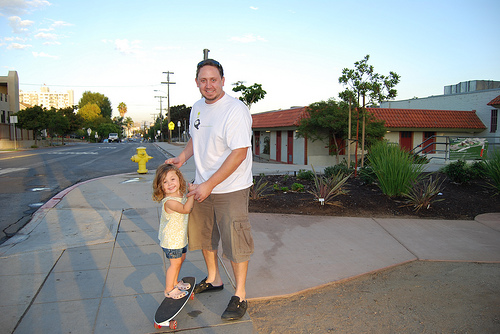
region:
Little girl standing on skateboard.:
[139, 155, 197, 332]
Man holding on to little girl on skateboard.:
[130, 55, 272, 329]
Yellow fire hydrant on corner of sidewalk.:
[100, 117, 182, 197]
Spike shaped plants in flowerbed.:
[235, 39, 498, 229]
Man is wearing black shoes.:
[162, 45, 266, 328]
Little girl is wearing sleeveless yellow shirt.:
[131, 142, 207, 327]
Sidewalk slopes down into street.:
[1, 156, 136, 286]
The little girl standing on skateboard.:
[133, 147, 198, 324]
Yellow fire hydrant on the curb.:
[116, 134, 159, 191]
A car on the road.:
[93, 125, 130, 145]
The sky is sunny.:
[52, 15, 266, 75]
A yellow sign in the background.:
[159, 113, 186, 143]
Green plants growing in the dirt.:
[375, 149, 417, 216]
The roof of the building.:
[375, 104, 498, 134]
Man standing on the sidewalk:
[162, 59, 254, 321]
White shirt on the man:
[187, 91, 254, 194]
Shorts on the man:
[186, 187, 255, 263]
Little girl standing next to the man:
[151, 160, 197, 299]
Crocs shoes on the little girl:
[164, 280, 191, 300]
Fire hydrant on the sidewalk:
[129, 146, 154, 173]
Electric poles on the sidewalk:
[148, 69, 178, 144]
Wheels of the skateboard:
[151, 292, 196, 329]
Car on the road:
[103, 130, 120, 145]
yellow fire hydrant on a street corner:
[128, 140, 154, 178]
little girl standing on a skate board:
[135, 162, 206, 328]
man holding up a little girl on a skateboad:
[148, 55, 251, 326]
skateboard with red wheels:
[141, 266, 197, 329]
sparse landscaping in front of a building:
[250, 155, 497, 220]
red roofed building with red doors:
[251, 105, 483, 173]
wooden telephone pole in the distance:
[157, 70, 175, 146]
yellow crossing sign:
[166, 120, 174, 130]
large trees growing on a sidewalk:
[18, 90, 123, 146]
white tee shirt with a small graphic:
[181, 91, 258, 199]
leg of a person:
[159, 253, 190, 293]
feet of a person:
[163, 288, 188, 299]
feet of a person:
[175, 273, 205, 290]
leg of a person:
[197, 228, 231, 275]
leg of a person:
[217, 223, 288, 293]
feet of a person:
[197, 268, 229, 295]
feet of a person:
[217, 285, 267, 330]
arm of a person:
[196, 135, 267, 196]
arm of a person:
[177, 128, 207, 162]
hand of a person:
[183, 179, 213, 210]